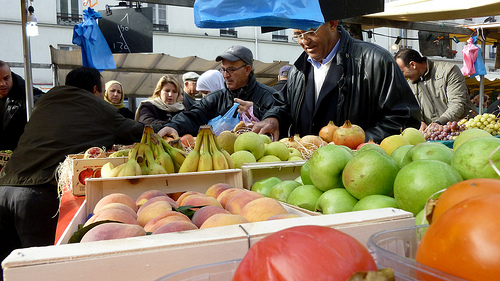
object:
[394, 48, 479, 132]
man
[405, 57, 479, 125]
jacket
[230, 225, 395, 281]
persimmons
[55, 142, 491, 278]
table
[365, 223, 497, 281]
box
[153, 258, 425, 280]
box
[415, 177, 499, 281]
tomatoes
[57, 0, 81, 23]
windows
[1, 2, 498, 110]
building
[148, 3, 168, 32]
windows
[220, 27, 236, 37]
windows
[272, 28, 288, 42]
windows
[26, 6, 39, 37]
light bulb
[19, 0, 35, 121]
pole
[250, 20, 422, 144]
man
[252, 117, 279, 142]
hand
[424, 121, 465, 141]
grapes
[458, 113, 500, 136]
grapes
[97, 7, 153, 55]
sign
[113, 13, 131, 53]
prices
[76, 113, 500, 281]
fruits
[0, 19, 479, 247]
people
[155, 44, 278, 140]
man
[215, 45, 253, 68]
hat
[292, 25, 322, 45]
glasses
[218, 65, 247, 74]
glasses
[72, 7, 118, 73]
bag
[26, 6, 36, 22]
holder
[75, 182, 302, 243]
peaches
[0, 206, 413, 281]
box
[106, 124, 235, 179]
bananas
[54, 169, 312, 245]
box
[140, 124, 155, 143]
stem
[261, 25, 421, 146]
jacket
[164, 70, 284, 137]
jacket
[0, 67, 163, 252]
man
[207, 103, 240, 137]
produce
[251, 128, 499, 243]
apples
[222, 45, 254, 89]
head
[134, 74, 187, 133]
woman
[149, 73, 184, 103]
hair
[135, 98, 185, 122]
scarf